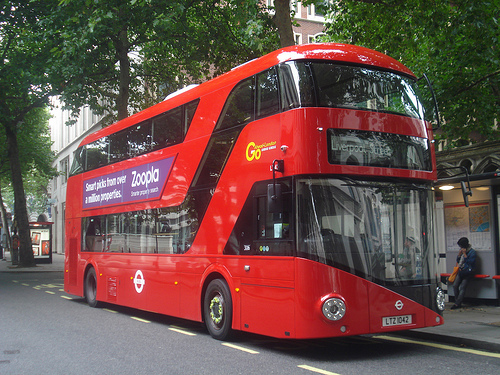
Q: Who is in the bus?
A: The driver.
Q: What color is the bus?
A: Red.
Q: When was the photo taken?
A: Daytime.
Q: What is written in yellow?
A: Go.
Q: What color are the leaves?
A: Green.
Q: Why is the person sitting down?
A: They are waiting for a bus.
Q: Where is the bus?
A: On the street.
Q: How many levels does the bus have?
A: Two.